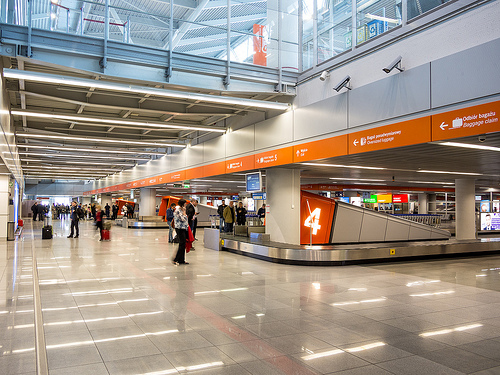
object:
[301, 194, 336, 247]
sign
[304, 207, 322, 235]
4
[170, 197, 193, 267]
woman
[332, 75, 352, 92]
video camera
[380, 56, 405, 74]
video camera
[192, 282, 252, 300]
light reflection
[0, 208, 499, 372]
floor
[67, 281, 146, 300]
light reflection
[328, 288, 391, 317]
light reflection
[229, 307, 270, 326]
light reflection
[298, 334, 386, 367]
light reflection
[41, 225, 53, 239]
bag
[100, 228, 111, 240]
bag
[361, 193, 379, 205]
sign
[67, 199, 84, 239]
person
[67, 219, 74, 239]
leg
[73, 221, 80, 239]
leg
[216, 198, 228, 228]
man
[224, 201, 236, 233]
man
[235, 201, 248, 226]
man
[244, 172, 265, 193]
television screen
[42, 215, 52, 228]
handle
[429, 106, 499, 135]
sign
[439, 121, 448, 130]
arrow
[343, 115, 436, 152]
sign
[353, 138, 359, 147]
arrow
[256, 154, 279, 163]
sign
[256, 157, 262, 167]
arrow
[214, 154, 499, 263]
baggage carousel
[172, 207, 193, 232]
top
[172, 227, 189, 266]
pants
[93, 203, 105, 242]
person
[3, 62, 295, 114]
light fixture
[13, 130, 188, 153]
light fixture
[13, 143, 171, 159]
light fixture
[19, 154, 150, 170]
light fixture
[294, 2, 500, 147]
wall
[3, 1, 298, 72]
window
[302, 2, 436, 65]
window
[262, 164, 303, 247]
pilliar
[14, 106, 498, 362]
baggage claim area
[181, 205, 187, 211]
phone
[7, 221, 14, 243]
trash can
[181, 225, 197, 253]
coat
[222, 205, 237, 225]
jacket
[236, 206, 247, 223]
coat